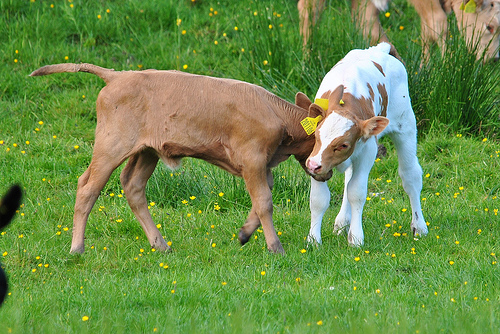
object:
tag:
[299, 113, 322, 137]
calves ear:
[326, 83, 346, 116]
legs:
[341, 137, 361, 219]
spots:
[364, 61, 391, 124]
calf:
[304, 40, 431, 250]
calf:
[296, 0, 499, 68]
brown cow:
[27, 62, 328, 255]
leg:
[388, 130, 428, 226]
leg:
[345, 133, 378, 223]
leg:
[306, 136, 335, 232]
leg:
[242, 152, 279, 241]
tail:
[28, 61, 115, 83]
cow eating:
[230, 94, 407, 207]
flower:
[362, 249, 368, 255]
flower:
[453, 239, 461, 246]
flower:
[449, 295, 457, 303]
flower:
[454, 185, 466, 190]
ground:
[389, 171, 454, 225]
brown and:
[306, 42, 428, 248]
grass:
[2, 0, 371, 333]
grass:
[377, 0, 498, 332]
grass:
[309, 263, 386, 332]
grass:
[173, 23, 274, 75]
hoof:
[238, 225, 250, 245]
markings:
[365, 82, 388, 122]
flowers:
[156, 1, 405, 76]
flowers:
[425, 182, 494, 215]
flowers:
[164, 194, 232, 214]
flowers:
[376, 211, 411, 243]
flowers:
[3, 115, 54, 158]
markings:
[324, 86, 381, 118]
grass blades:
[417, 24, 497, 123]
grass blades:
[229, 14, 356, 74]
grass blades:
[157, 166, 242, 216]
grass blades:
[267, 167, 308, 207]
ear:
[305, 102, 324, 131]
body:
[77, 74, 274, 212]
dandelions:
[354, 254, 362, 262]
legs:
[243, 170, 271, 233]